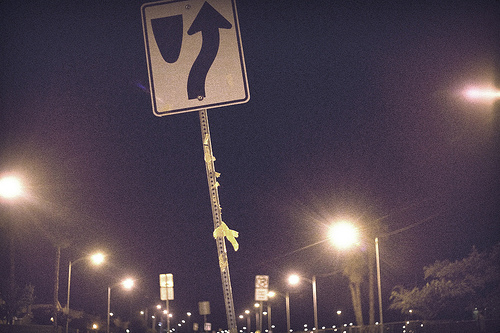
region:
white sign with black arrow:
[138, 4, 253, 109]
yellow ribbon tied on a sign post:
[213, 217, 246, 257]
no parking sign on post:
[253, 271, 271, 291]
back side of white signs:
[152, 268, 184, 323]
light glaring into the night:
[314, 205, 371, 257]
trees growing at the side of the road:
[386, 250, 484, 307]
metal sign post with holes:
[193, 120, 250, 312]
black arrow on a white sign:
[179, 1, 234, 131]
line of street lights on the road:
[241, 233, 386, 318]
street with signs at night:
[100, 253, 360, 325]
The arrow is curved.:
[184, 0, 227, 112]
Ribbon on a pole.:
[208, 216, 243, 255]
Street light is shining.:
[311, 205, 375, 258]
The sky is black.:
[285, 42, 392, 119]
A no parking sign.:
[249, 269, 274, 303]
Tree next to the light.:
[407, 258, 498, 318]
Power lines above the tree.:
[278, 180, 489, 255]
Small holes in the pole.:
[197, 108, 215, 150]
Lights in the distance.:
[297, 300, 429, 330]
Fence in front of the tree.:
[396, 302, 496, 330]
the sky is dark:
[31, 20, 128, 65]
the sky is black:
[275, 25, 345, 80]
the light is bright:
[442, 56, 498, 126]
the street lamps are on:
[7, 167, 178, 325]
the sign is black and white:
[140, 5, 257, 121]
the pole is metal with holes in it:
[190, 120, 238, 330]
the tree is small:
[385, 245, 484, 316]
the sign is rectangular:
[138, 5, 253, 121]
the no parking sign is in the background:
[248, 270, 278, 305]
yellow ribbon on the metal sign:
[201, 210, 259, 265]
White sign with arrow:
[138, 1, 252, 121]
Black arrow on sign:
[183, 4, 238, 100]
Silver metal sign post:
[195, 106, 247, 331]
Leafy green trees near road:
[387, 251, 498, 321]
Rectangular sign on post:
[249, 273, 271, 326]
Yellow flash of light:
[307, 208, 383, 261]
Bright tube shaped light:
[452, 83, 499, 105]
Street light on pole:
[60, 237, 111, 326]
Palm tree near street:
[37, 156, 75, 328]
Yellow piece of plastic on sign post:
[212, 211, 247, 253]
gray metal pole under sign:
[199, 107, 236, 331]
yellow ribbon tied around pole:
[212, 221, 242, 250]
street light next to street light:
[62, 248, 108, 330]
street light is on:
[87, 249, 106, 267]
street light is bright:
[325, 215, 363, 250]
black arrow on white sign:
[185, 2, 235, 99]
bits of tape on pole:
[202, 144, 216, 171]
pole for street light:
[62, 260, 75, 330]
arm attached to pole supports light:
[70, 255, 90, 268]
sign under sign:
[252, 284, 268, 301]